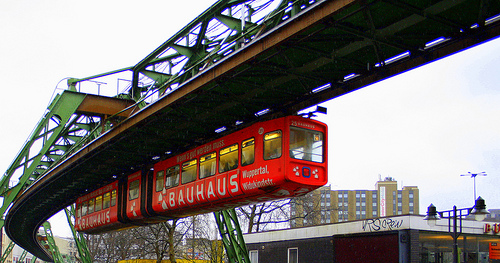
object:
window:
[246, 251, 257, 263]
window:
[288, 250, 297, 261]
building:
[245, 214, 497, 263]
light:
[313, 169, 319, 179]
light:
[293, 166, 299, 176]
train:
[64, 116, 327, 232]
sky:
[88, 23, 122, 47]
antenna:
[460, 171, 487, 205]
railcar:
[12, 75, 350, 263]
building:
[291, 174, 420, 230]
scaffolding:
[30, 74, 96, 162]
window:
[263, 130, 282, 160]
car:
[70, 104, 330, 235]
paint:
[152, 164, 249, 209]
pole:
[448, 205, 464, 263]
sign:
[301, 167, 311, 177]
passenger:
[242, 153, 255, 166]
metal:
[52, 91, 90, 139]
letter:
[240, 165, 269, 177]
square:
[289, 161, 324, 181]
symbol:
[292, 163, 300, 177]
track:
[189, 76, 323, 159]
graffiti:
[362, 217, 403, 232]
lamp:
[424, 204, 442, 227]